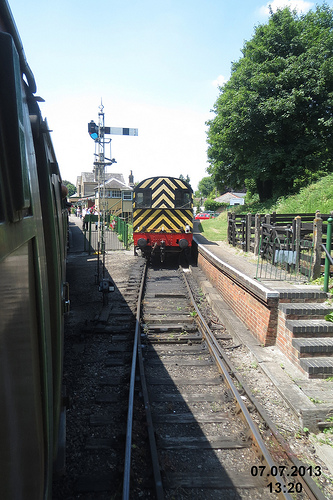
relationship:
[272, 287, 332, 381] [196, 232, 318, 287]
ladders leading up to platform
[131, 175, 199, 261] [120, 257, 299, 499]
train on track track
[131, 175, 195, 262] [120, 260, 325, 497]
train on track tracks